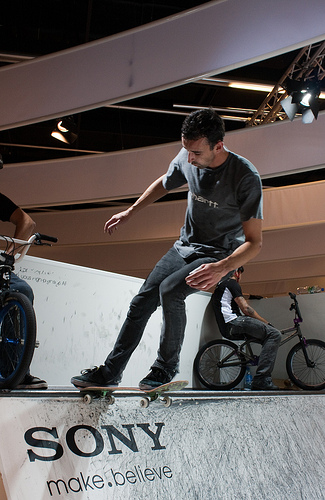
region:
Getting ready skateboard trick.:
[77, 106, 231, 418]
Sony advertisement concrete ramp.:
[13, 417, 180, 492]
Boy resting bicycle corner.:
[202, 259, 324, 387]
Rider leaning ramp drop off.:
[109, 107, 267, 332]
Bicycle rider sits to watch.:
[3, 168, 65, 396]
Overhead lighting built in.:
[231, 54, 323, 149]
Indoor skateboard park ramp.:
[23, 213, 321, 494]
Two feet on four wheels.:
[69, 359, 193, 409]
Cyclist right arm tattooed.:
[227, 292, 275, 337]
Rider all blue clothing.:
[139, 140, 269, 388]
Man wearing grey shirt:
[219, 167, 254, 203]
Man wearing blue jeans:
[123, 304, 185, 348]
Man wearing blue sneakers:
[66, 359, 122, 387]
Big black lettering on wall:
[19, 419, 171, 461]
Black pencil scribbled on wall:
[208, 421, 278, 471]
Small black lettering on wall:
[40, 462, 181, 495]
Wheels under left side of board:
[78, 392, 121, 407]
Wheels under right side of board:
[138, 395, 174, 413]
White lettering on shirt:
[182, 182, 224, 216]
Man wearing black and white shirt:
[216, 285, 234, 330]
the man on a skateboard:
[68, 107, 267, 405]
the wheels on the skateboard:
[80, 393, 177, 415]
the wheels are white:
[76, 391, 185, 412]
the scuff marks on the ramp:
[190, 409, 313, 484]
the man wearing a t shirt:
[54, 147, 278, 376]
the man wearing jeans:
[87, 151, 268, 365]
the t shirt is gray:
[139, 143, 286, 266]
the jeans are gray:
[54, 226, 235, 405]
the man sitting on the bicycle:
[183, 261, 320, 391]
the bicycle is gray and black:
[193, 287, 320, 395]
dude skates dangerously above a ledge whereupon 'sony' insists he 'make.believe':
[40, 99, 276, 407]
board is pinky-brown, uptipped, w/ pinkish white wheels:
[72, 378, 197, 410]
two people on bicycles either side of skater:
[0, 148, 324, 397]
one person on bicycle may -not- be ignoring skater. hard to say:
[0, 172, 66, 394]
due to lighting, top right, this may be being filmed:
[236, 39, 321, 136]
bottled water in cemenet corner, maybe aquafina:
[239, 364, 252, 386]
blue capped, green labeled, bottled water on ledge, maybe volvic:
[293, 278, 322, 295]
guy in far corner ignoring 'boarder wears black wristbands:
[249, 288, 274, 329]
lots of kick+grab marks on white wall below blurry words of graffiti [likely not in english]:
[9, 258, 203, 386]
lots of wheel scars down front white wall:
[35, 392, 324, 498]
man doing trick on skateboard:
[94, 112, 248, 380]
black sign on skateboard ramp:
[14, 412, 179, 485]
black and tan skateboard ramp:
[185, 407, 313, 476]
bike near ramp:
[0, 227, 58, 370]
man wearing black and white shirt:
[188, 175, 232, 244]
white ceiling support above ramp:
[21, 62, 155, 86]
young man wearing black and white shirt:
[214, 283, 239, 321]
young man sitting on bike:
[219, 286, 315, 378]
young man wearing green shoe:
[74, 368, 115, 386]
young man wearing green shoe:
[139, 370, 162, 388]